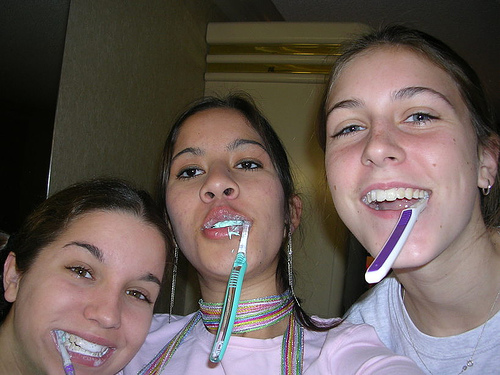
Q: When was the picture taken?
A: Morning.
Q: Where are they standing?
A: Bathroom.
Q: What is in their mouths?
A: Toothbrushes.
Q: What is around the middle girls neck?
A: Scarf.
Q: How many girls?
A: Three.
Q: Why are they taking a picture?
A: For fun.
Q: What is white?
A: Teeth.